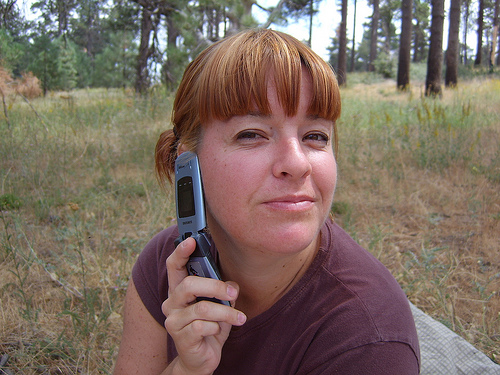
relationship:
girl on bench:
[112, 28, 418, 374] [404, 296, 499, 375]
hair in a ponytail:
[154, 25, 343, 190] [153, 126, 188, 192]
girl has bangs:
[118, 26, 413, 374] [198, 28, 343, 125]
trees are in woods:
[5, 0, 499, 96] [5, 0, 499, 101]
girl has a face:
[118, 26, 413, 374] [200, 61, 338, 254]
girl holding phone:
[118, 26, 413, 374] [172, 149, 235, 316]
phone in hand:
[172, 149, 235, 316] [159, 238, 247, 370]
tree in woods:
[132, 0, 168, 92] [5, 0, 499, 101]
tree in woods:
[0, 0, 168, 92] [5, 0, 499, 101]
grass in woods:
[0, 76, 499, 375] [5, 0, 499, 101]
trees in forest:
[5, 0, 499, 96] [6, 0, 498, 111]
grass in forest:
[7, 76, 498, 373] [6, 0, 498, 111]